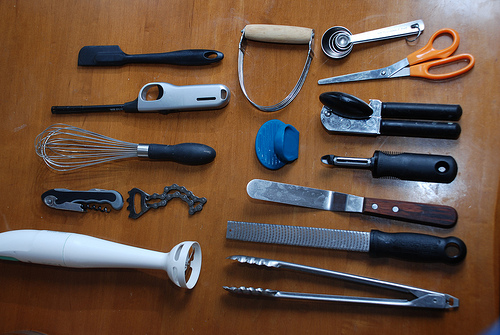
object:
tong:
[223, 254, 459, 311]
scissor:
[316, 28, 476, 87]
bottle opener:
[127, 183, 207, 219]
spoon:
[321, 19, 425, 59]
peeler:
[320, 148, 459, 184]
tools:
[0, 18, 478, 309]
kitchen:
[0, 0, 500, 335]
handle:
[381, 102, 463, 140]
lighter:
[50, 81, 232, 118]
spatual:
[255, 119, 299, 171]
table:
[0, 0, 500, 335]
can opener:
[319, 90, 464, 139]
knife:
[317, 150, 457, 184]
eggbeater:
[33, 124, 217, 172]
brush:
[0, 229, 203, 290]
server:
[237, 21, 316, 112]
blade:
[247, 178, 365, 213]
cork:
[77, 44, 224, 66]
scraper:
[224, 218, 467, 265]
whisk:
[41, 188, 124, 213]